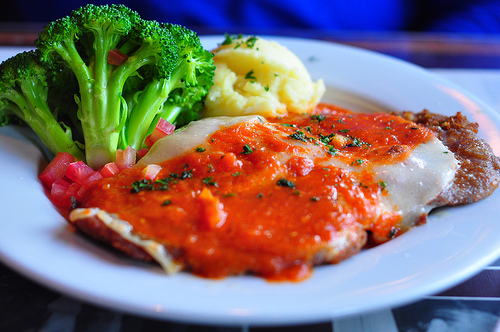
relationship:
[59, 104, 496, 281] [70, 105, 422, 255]
meat covered with a sauce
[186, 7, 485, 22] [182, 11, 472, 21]
person wearing blue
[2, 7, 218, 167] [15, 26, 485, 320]
broccoli on plate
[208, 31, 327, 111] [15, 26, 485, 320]
potatoes on plate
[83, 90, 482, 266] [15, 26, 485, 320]
pasta on plate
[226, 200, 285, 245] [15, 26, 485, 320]
pasta sauce on plate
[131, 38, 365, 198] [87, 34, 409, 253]
seasoning on food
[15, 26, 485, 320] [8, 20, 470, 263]
plate with food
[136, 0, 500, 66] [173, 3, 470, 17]
person wearing shirt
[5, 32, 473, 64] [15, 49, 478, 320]
edge on table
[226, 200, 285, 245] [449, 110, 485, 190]
pasta sauce on veal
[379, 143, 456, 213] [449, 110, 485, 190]
cheese on veal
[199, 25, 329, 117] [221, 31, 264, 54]
mashed potato on parsley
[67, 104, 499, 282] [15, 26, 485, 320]
chicken on plate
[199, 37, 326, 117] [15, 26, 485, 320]
mashed potato on plate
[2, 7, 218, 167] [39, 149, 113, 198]
broccoli next radish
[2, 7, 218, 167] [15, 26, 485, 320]
broccoli next plate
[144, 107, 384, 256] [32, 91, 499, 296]
dressing on food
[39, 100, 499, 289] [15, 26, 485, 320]
meat on plate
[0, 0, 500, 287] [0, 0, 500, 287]
food touch food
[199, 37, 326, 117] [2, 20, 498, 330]
mashed potato on plate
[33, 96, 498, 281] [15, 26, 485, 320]
food on plate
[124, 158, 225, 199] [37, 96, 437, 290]
herb on tomato sauce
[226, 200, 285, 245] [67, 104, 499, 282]
pasta sauce on chicken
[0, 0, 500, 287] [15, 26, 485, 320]
food on a plate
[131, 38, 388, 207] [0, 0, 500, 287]
seasoning on food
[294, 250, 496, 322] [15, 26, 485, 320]
edge of plate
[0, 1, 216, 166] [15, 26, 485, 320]
broccoli on plate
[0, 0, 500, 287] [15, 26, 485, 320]
food on plate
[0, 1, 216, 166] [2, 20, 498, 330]
broccoli on plate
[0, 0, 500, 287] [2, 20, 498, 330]
food on plate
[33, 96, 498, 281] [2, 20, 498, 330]
food on plate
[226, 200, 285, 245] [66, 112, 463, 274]
pasta sauce on meat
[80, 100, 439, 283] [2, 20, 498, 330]
pasta sauce on plate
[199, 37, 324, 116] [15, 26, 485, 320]
potatoes on plate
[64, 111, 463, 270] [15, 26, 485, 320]
chicken on plate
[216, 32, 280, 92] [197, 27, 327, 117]
onions on potatoes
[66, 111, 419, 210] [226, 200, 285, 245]
chives on pasta sauce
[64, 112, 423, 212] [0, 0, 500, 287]
toppings on food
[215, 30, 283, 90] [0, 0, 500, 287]
toppings on food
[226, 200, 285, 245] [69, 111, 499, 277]
pasta sauce on chicken